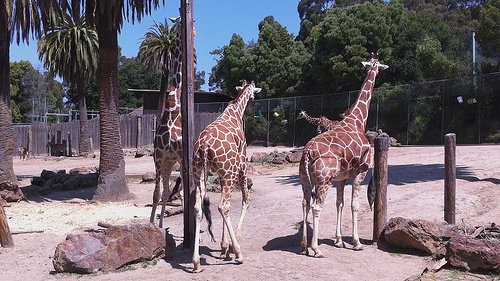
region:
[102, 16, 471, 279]
four giraffes in the cage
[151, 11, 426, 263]
three giraffes in the front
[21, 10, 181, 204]
these are palm trees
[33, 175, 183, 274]
a large sandstone rock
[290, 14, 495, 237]
the giraffe stands near wooden posts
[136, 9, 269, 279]
the giraffes are by a pole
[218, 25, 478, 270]
trees are behind the fence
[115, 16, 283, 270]
there are two giraffes in this box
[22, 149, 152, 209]
the shadow of the palm tree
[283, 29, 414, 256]
this giraffe is fat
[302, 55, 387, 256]
the giraffe is looking at the distance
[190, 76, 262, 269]
the giraffe is walking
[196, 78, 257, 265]
the giraffe is taking a step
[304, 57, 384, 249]
the giraffe is standing still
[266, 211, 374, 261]
a shadow is on the ground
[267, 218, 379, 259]
the giraffe is casting a shadow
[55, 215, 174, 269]
a rock is on the ground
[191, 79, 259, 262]
the giraffe is heading away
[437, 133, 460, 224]
a pole is besides the giraffe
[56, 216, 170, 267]
a large rock is on the ground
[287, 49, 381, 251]
a tall giraffe standing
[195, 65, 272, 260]
a giraffe in the middle of walking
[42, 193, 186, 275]
a large sized boulder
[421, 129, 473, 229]
a short wooden post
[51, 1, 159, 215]
a large standing palm tree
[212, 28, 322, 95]
a large green oak tree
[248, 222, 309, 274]
a ground made of sand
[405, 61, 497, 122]
a metal fenced gate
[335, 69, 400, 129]
the long neck of a giraffe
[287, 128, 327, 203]
the tail of a giraffe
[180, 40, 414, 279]
A group of giraffes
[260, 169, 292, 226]
A brown dirt ground surface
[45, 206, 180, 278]
A large brown rock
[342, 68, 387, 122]
A giraffe's long neck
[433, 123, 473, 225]
A brown wooden post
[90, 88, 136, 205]
The brown trunk of a palm tree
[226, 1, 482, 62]
Green trees in the background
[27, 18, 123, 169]
A palm tree with green leaves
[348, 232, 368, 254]
A giraffe's front hoof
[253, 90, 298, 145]
A metal chain link fence